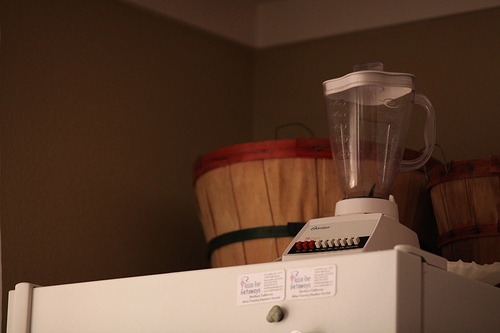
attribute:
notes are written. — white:
[232, 266, 341, 306]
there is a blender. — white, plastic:
[281, 62, 439, 253]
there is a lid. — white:
[323, 62, 417, 96]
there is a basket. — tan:
[190, 123, 444, 268]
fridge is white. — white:
[3, 245, 499, 331]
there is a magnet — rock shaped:
[265, 304, 285, 324]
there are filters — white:
[446, 256, 499, 288]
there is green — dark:
[206, 221, 310, 262]